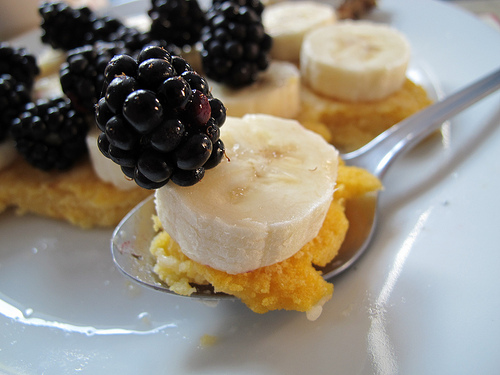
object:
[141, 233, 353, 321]
fritter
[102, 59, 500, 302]
spoon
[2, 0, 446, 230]
topping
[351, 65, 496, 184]
handle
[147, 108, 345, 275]
bananna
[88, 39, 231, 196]
blackberry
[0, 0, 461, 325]
breakfast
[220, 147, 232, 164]
stem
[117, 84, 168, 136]
berries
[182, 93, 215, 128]
sement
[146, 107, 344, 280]
slice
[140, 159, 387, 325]
crust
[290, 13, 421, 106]
slices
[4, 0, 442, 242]
pancake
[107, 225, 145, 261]
tip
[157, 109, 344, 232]
top